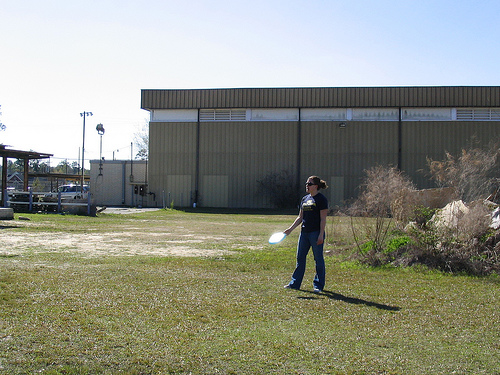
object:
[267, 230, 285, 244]
frisbee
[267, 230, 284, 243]
sunlight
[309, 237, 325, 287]
leg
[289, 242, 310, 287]
leg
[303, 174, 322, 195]
head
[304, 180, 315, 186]
sunglasses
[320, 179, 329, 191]
ponytail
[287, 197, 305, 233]
arm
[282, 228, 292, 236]
hand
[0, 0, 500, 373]
background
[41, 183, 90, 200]
van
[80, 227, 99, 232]
spot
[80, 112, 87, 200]
light pole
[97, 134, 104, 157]
light pole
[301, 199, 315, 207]
logo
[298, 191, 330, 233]
shirt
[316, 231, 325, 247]
hand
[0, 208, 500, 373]
grassy area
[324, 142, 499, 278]
bush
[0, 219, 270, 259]
dirt area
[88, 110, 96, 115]
lights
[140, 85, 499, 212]
building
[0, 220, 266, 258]
dirt patch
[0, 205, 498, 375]
grass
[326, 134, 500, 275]
weeds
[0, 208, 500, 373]
field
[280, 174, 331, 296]
girl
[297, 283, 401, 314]
shadow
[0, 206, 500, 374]
ground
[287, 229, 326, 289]
jeans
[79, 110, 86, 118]
light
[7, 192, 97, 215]
fence